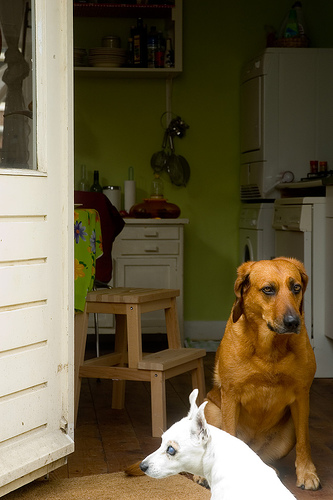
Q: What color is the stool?
A: Tan.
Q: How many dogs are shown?
A: Two.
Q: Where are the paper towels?
A: On counter.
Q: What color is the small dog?
A: White.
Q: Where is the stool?
A: On floor.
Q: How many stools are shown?
A: One.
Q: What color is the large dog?
A: Brown.